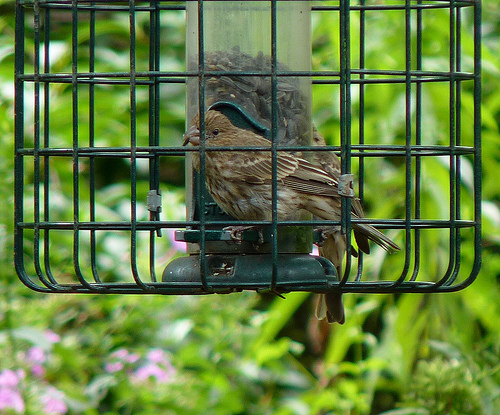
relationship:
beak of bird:
[183, 127, 201, 145] [177, 111, 384, 271]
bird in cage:
[182, 108, 401, 260] [9, 9, 473, 299]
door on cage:
[155, 10, 354, 230] [9, 9, 473, 299]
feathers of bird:
[234, 151, 297, 184] [186, 113, 378, 245]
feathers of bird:
[230, 151, 338, 212] [189, 117, 384, 273]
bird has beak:
[156, 56, 391, 275] [177, 124, 199, 148]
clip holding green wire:
[333, 171, 358, 198] [340, 0, 347, 178]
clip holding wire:
[333, 171, 358, 198] [346, 91, 351, 171]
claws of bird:
[224, 221, 239, 231] [228, 127, 386, 257]